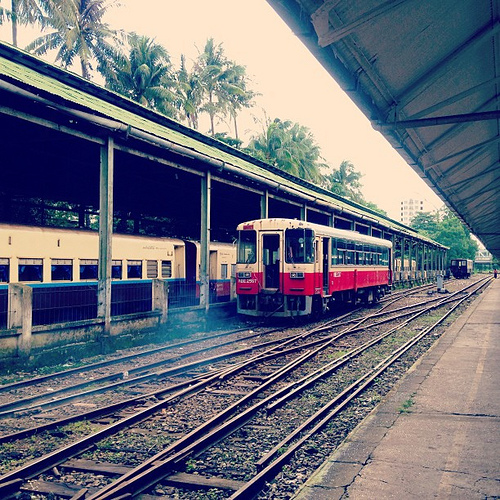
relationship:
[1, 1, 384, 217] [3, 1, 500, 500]
palm trees are behind station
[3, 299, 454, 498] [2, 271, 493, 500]
grass growing between tracks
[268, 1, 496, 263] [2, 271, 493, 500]
roofing to right of tracks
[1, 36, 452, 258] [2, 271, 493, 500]
roofing to left side of tracks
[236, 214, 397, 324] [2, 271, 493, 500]
trains on tracks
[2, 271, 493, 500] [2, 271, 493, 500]
tracks are on ground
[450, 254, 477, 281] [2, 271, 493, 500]
trains are on tracks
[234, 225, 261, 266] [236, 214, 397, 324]
window on trains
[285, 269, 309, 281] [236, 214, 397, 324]
light on trains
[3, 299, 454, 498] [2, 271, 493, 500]
grass between tracks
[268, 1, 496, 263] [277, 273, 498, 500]
awning hanging above platform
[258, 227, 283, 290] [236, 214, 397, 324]
train door on trains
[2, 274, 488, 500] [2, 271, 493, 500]
gravel along tracks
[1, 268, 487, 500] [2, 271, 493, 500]
wood between tracks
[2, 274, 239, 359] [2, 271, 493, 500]
fence alongside tracks